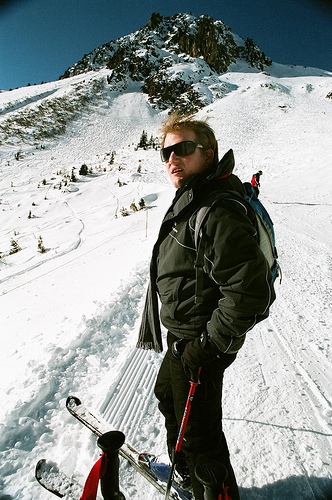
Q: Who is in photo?
A: Man.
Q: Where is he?
A: Snowy mountain.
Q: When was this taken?
A: Daytime.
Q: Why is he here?
A: Ski.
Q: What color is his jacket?
A: Black.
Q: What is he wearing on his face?
A: Sunglasses.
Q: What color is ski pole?
A: Red.